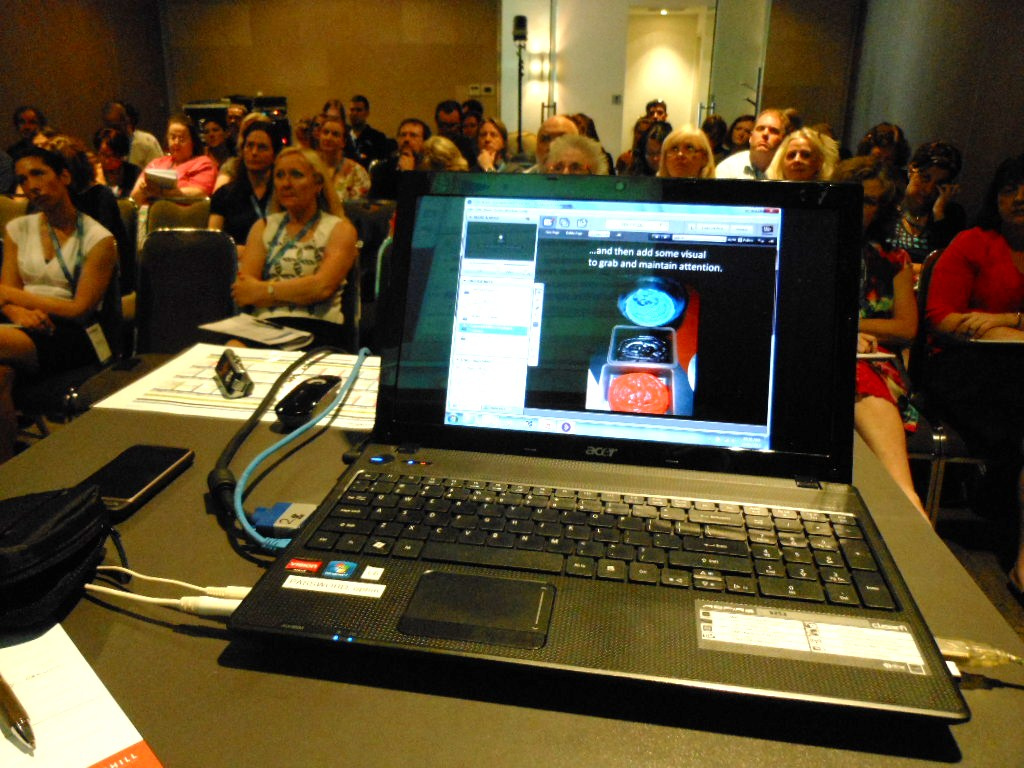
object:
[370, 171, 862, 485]
black computer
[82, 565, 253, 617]
cord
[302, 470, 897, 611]
keyboard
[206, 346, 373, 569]
cord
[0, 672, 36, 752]
pen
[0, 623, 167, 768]
paper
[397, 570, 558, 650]
black touchpad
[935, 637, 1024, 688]
cable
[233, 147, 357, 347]
woman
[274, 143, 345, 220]
hair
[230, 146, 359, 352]
people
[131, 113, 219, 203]
woman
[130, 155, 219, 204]
shirt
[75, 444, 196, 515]
phone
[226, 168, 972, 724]
laptop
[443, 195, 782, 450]
computer program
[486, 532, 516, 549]
keys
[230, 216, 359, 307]
arms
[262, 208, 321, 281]
lanyard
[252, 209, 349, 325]
shirt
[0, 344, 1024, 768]
table